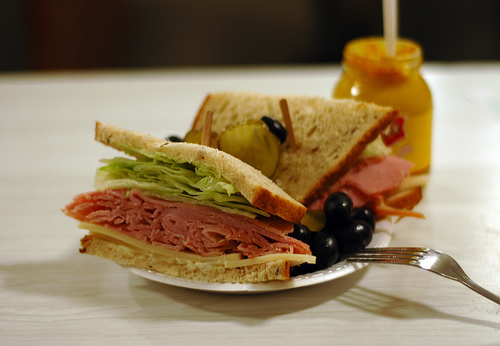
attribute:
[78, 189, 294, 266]
meat — mound, sliced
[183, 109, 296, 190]
pickles — dill, slices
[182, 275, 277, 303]
plate — white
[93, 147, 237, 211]
lettuce — Stack, green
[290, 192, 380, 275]
olives — small, pile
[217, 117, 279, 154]
pickle — sliced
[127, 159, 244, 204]
lettuce — green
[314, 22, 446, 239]
jar — open, mustard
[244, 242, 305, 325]
cheese — Slices, white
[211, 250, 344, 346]
plate — styrofoam